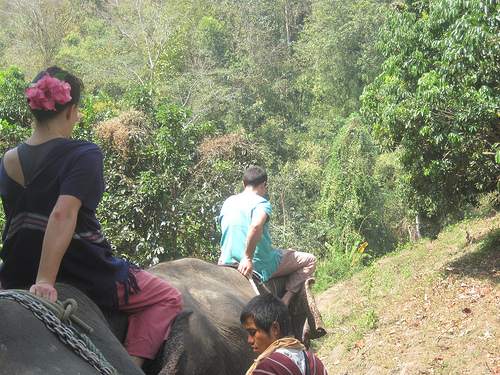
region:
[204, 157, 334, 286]
This is a person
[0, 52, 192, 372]
This is a person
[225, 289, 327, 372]
This is a person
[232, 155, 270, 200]
Head of a person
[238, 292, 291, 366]
Head of a person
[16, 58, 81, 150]
Head of a person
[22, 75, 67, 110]
The flower on the woman's head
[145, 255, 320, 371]
The elephant in the lead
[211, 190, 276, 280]
The blue shirt on the boy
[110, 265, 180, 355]
The pink pants on the woman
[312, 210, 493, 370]
The hillside by the people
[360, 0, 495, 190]
The closest tree on the right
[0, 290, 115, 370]
The chains on the elephant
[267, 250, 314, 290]
The pink pants on the boy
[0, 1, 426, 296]
The forest in front of the people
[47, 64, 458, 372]
this is a jungle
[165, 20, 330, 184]
the jungle is green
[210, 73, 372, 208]
the trees are thick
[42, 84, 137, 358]
the woman is riding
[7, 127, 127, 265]
the shirt is black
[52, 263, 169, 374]
the woman is riding an elephant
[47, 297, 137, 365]
the elephant is gray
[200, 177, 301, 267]
the person is riding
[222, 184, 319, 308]
the shirt is turqoise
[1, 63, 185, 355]
The woman is riding a elephants.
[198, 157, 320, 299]
The man is riding the elephant.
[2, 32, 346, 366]
people riding on an elephant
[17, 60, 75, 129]
flowers on the back of a woman's hair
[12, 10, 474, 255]
trees on the side of a hill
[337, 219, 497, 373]
dirt, leaves, and grass on the side of a hill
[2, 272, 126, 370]
chains on the side of an elephant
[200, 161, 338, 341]
a man riding the front of an elephant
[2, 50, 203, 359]
a woman riding on an elephant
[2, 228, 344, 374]
two elephants walking in the wilderness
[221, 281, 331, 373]
a man guiding elephants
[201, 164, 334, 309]
person wearing khaki pants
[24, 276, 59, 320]
a hand holding the chain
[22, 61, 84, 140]
A woman with the flower in her hair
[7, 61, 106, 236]
The back of a woman with the flower in her hair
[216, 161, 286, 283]
A man holding onto an elephant seat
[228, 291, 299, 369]
A man looking at an elephant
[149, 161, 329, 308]
a man riding on an elephant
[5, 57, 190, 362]
a lady with pink pants on an elephant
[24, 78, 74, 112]
pink flower behind head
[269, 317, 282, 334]
a little left ear of boy